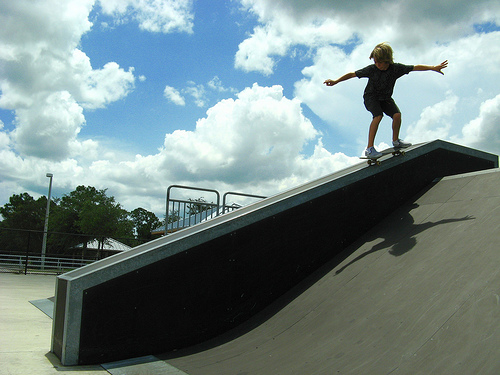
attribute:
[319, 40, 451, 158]
kid — small, young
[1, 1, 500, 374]
picture — daylight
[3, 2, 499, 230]
sky — sunny, blue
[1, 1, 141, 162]
clouds — white, puffy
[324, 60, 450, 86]
arms — out, extended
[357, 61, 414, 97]
shirt — black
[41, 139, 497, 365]
wall — gray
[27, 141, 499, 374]
ramp — concrete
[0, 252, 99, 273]
fence — metal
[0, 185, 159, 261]
leaves — green